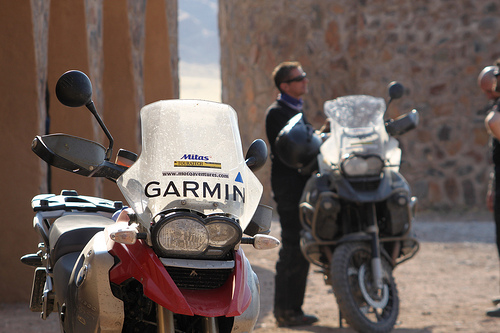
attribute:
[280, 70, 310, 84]
sun glasses — black 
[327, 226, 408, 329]
tire — black 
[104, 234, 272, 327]
fender — red 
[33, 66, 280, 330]
motorcycle — unattended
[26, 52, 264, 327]
motorcycle — unoccupied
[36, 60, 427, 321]
motorbikes — parked 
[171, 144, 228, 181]
"mitas" logo — mitas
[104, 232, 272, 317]
red motorcycle — white and red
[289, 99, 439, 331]
black motorcycle — black 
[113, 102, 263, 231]
white wind shield — white 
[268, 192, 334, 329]
denim jeans — black, cotton , denim 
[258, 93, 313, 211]
black jacket — black 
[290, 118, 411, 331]
motorcycle — parked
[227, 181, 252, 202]
letter — black